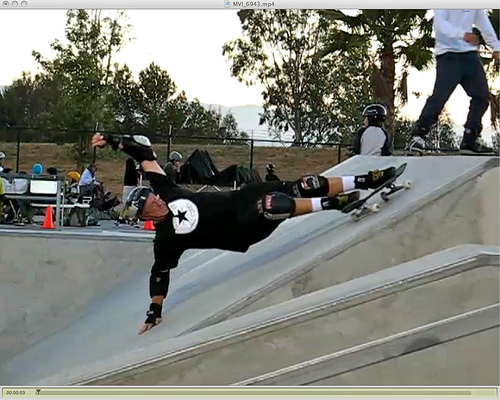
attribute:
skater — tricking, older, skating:
[91, 129, 413, 337]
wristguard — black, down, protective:
[144, 303, 164, 328]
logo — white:
[165, 197, 201, 239]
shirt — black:
[141, 167, 245, 275]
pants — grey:
[412, 47, 490, 142]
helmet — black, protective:
[124, 184, 155, 224]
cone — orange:
[41, 204, 55, 232]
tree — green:
[39, 5, 130, 159]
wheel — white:
[400, 177, 413, 191]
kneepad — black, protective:
[257, 192, 295, 220]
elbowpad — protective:
[121, 131, 157, 164]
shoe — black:
[365, 167, 396, 191]